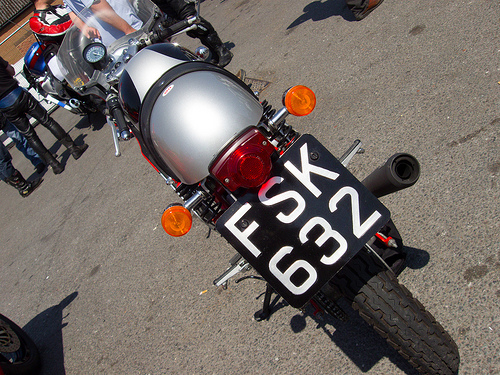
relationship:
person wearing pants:
[1, 57, 91, 172] [3, 89, 78, 169]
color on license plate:
[223, 142, 384, 296] [209, 127, 396, 313]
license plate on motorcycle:
[214, 140, 401, 307] [19, 23, 499, 370]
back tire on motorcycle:
[331, 253, 469, 370] [19, 23, 499, 370]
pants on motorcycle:
[3, 89, 68, 157] [82, 16, 432, 306]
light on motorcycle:
[211, 128, 275, 192] [49, 0, 457, 374]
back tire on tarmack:
[328, 247, 459, 374] [3, 0, 496, 370]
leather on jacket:
[39, 23, 51, 32] [30, 5, 76, 42]